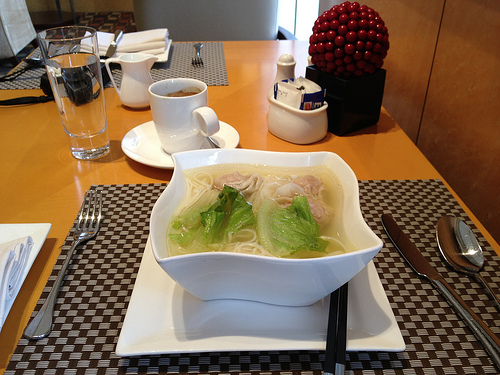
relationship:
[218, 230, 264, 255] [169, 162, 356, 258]
noodles in soup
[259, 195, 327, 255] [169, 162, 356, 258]
leaf in soup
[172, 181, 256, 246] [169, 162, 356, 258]
leaf in soup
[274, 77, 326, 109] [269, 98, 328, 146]
sweetner in container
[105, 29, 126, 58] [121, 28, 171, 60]
knife on napkin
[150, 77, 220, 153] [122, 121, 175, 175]
cup on saucer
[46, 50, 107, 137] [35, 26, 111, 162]
liquid in glass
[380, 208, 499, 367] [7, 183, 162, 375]
knife on placemat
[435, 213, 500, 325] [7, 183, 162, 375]
spoon on placemat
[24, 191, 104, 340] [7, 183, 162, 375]
fork on placemat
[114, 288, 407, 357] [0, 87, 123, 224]
plate on table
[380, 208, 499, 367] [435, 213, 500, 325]
knife near spoon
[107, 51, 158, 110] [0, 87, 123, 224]
pitcher on table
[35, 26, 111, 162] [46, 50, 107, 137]
glass full of liquid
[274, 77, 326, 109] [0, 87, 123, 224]
sweetner on table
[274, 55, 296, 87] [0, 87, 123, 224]
salt shaker on table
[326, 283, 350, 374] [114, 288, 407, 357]
chopsticks on plate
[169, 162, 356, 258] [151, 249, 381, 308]
soup in bowl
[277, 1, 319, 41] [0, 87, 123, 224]
window behind table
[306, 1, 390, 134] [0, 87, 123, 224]
decoration on table